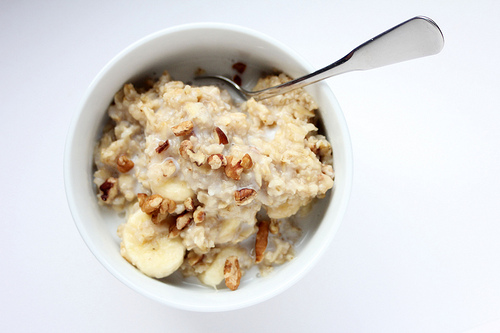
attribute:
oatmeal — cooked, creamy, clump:
[98, 64, 328, 294]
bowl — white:
[64, 18, 353, 317]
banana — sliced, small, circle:
[121, 210, 188, 276]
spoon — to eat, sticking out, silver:
[187, 15, 449, 105]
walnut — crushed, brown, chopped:
[153, 193, 175, 224]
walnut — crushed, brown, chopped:
[139, 189, 162, 218]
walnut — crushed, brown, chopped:
[173, 208, 194, 233]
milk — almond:
[105, 61, 312, 282]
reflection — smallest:
[255, 79, 304, 102]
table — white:
[0, 2, 498, 333]